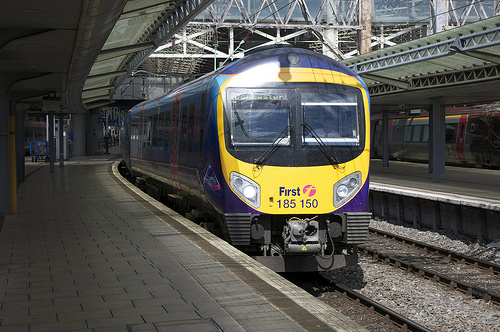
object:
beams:
[229, 27, 235, 58]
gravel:
[490, 313, 498, 317]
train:
[119, 47, 374, 271]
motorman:
[306, 115, 341, 137]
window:
[302, 92, 361, 145]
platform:
[370, 158, 499, 211]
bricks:
[140, 310, 202, 323]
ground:
[0, 144, 499, 331]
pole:
[8, 116, 17, 215]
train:
[370, 99, 499, 168]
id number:
[283, 199, 289, 209]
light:
[243, 185, 258, 199]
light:
[336, 184, 350, 198]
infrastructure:
[148, 21, 363, 59]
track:
[325, 278, 433, 331]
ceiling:
[110, 0, 499, 100]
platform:
[0, 145, 369, 331]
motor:
[280, 215, 322, 253]